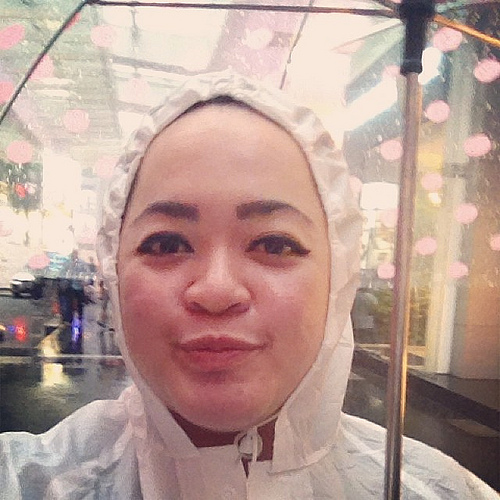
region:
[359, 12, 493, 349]
Pink doted umbrella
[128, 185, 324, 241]
Well manicured eyebrows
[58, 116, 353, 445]
Young woman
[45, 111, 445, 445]
Young woman in the rain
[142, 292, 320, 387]
duck face selfie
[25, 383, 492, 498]
girl wearing white poncho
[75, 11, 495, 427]
Young woman at shopping center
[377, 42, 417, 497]
Metal umbrella pole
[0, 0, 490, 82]
Clear umbrella with pink polka dots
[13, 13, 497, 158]
rainy and overcast weather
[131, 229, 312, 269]
woman wears black eyeliner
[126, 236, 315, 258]
woman wears subtle false eyelashes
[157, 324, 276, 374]
smiling or smirking woman wears no lipstick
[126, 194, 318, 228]
woman has well-sculpted eyebrows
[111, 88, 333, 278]
almost all of woman's hair+hairline hidden by light white rain parka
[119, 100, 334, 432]
woman's very clear skin turns ruddyish+slightly imperfect towards central face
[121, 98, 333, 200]
woman has high forehead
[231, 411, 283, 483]
woman's thin white parka hood tied around neck with a string ending in some sort of device [?]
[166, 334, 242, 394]
shadow of pursed lips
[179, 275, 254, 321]
bottom of woman's nose spreads slightly due to lips pursing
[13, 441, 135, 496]
White raincoat on the woman's right shoulder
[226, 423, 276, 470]
Tie from the raincoats hood under the woman's chin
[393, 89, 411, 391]
Silver pole/handle of the woman's umbrella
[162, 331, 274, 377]
Woman's red smiling lips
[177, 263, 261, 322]
Woman's pudgy nose in the center of her face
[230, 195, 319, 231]
Woman's nicely groomed left eyebrow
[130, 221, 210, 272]
Woman's pretty brown right eye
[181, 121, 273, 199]
Woman's bare high forehead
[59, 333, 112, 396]
Wet ground in the background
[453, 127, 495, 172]
Pink dot on the transparent umbrella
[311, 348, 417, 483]
over coat is white in color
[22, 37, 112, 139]
umbrella has pink spots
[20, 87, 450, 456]
it is a rainy day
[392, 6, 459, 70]
knob is black in color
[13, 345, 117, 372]
white lines are in road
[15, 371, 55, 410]
road is wet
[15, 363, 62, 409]
road is grey color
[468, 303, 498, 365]
wall is brown color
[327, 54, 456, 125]
lights are on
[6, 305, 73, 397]
reflection is seen on road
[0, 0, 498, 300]
Pink polka dotted opaque umbrella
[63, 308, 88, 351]
Long purple light in background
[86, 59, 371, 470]
White hood of the person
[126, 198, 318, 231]
Eyebrows of person under the umbrella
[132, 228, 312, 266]
Eyes of person under the umbrella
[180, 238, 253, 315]
Nose of person under the umbrella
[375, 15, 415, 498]
The umbrella pole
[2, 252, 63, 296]
Car in the background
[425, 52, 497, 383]
White wall on the right side of the photo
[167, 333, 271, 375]
Mouth of person under the umbrella